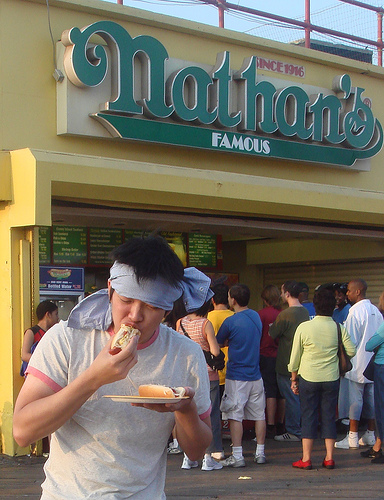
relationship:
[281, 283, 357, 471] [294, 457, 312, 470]
woman wearing red shoe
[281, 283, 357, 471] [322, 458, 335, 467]
woman wearing red shoe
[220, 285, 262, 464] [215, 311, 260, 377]
man wearing shirt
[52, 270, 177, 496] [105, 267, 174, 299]
man with cloth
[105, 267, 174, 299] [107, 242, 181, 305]
cloth tied around head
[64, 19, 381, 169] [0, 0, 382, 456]
sign on building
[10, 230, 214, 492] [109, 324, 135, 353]
man biting hotdog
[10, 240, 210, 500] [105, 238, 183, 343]
person has head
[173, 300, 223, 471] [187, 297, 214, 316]
person has head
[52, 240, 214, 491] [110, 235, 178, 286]
person has head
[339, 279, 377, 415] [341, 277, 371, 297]
person has head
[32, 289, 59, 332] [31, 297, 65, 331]
perosn has head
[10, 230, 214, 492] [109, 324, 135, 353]
man enjoying hotdog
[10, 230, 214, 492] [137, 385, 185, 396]
man enjoying sandwich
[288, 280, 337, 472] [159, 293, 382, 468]
person waits in line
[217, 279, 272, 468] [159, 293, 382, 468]
person waits in line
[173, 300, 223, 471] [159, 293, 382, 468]
person waits in line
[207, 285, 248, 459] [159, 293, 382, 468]
person waits in line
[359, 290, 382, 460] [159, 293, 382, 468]
person waits in line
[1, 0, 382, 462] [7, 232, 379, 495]
nathan's packed with people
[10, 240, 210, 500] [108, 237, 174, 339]
person has head